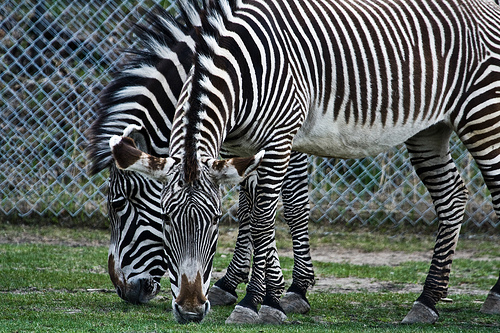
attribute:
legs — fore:
[220, 125, 400, 331]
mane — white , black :
[60, 8, 237, 198]